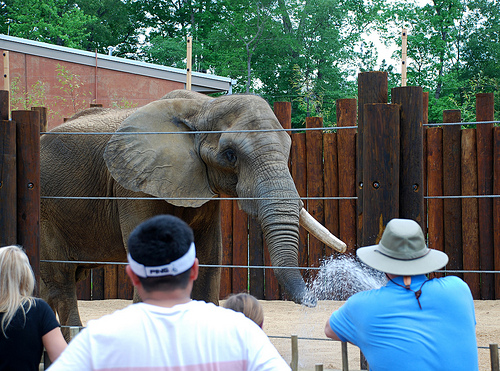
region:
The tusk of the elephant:
[300, 203, 350, 258]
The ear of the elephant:
[101, 98, 221, 208]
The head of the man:
[119, 215, 211, 298]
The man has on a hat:
[354, 215, 453, 277]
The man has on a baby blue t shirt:
[327, 272, 481, 369]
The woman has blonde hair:
[1, 239, 39, 339]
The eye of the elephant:
[212, 135, 243, 170]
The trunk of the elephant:
[245, 168, 326, 308]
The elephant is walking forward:
[34, 77, 347, 348]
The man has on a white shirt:
[38, 298, 293, 368]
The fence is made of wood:
[296, 68, 498, 300]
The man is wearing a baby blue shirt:
[322, 275, 481, 369]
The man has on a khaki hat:
[353, 215, 450, 279]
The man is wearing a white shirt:
[41, 303, 293, 368]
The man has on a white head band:
[121, 213, 203, 300]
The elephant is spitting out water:
[273, 252, 384, 313]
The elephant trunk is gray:
[255, 166, 319, 322]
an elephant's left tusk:
[290, 192, 357, 254]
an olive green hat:
[352, 206, 456, 291]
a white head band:
[117, 242, 203, 272]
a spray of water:
[296, 245, 385, 319]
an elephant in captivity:
[32, 101, 342, 338]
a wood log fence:
[72, 103, 485, 296]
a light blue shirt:
[324, 280, 479, 364]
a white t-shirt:
[65, 297, 277, 369]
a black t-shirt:
[5, 292, 53, 369]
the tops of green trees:
[55, 11, 497, 97]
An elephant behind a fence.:
[5, 88, 347, 368]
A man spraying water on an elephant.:
[327, 218, 474, 369]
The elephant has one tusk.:
[225, 197, 346, 253]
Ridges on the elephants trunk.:
[243, 131, 309, 301]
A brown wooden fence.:
[216, 72, 496, 297]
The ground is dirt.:
[26, 295, 493, 361]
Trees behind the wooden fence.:
[53, 37, 496, 109]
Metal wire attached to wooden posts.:
[17, 103, 495, 318]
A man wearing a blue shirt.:
[327, 275, 474, 368]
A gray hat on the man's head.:
[355, 219, 448, 271]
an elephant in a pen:
[23, 82, 334, 333]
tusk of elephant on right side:
[290, 198, 350, 257]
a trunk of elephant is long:
[236, 165, 326, 311]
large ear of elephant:
[97, 90, 213, 211]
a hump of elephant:
[140, 75, 238, 132]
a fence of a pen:
[3, 73, 498, 300]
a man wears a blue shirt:
[316, 212, 488, 369]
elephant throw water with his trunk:
[189, 90, 376, 313]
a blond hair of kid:
[220, 272, 276, 337]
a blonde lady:
[0, 242, 70, 368]